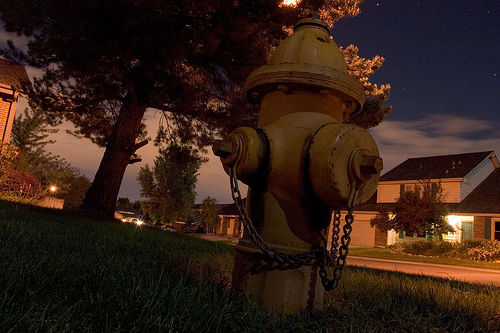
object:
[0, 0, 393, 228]
tree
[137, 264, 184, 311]
grass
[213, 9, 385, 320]
hydrant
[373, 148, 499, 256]
house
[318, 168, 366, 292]
chain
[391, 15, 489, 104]
sky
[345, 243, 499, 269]
garden